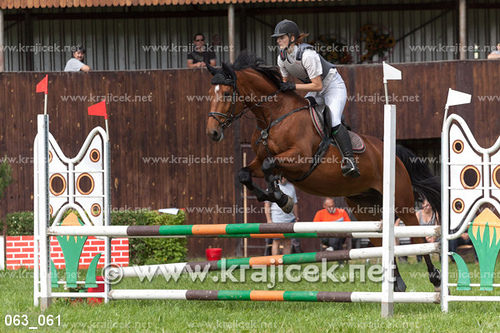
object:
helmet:
[271, 17, 301, 39]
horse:
[202, 57, 441, 293]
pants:
[303, 68, 350, 128]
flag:
[87, 98, 109, 118]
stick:
[46, 220, 383, 237]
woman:
[271, 18, 360, 178]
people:
[63, 44, 92, 72]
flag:
[446, 88, 473, 107]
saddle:
[307, 102, 367, 154]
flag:
[383, 59, 402, 84]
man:
[186, 33, 217, 71]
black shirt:
[187, 45, 217, 68]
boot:
[331, 123, 360, 173]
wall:
[0, 233, 129, 274]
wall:
[0, 0, 499, 73]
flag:
[35, 74, 50, 94]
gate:
[33, 115, 111, 302]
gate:
[441, 113, 500, 313]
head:
[206, 63, 248, 144]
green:
[159, 225, 192, 235]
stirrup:
[339, 154, 355, 177]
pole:
[35, 112, 51, 312]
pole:
[381, 104, 398, 318]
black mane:
[215, 56, 293, 90]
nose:
[212, 130, 219, 138]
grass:
[1, 257, 500, 332]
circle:
[75, 171, 95, 195]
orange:
[192, 224, 227, 235]